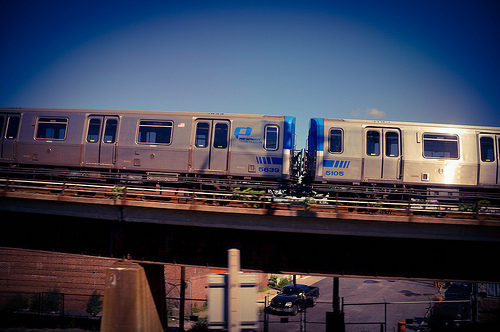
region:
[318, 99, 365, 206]
gray elevated train on track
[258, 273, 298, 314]
black pick up truck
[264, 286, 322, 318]
black truck under bridge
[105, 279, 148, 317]
concrete support partition of bridge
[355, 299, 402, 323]
fence is under bridge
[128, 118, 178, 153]
window of gray train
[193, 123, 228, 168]
doors of elevated train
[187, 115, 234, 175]
Silver automatic doors on a silver train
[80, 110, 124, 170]
Silver automatic doors on a silver train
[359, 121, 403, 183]
Silver automatic doors on a silver train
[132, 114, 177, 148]
Passenger window on a silver train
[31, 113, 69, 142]
Passenger window on a silver train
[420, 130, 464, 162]
Passenger window on a silver train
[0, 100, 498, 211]
Silver passenger train traveling down track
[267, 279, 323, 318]
Black ford pickup on the road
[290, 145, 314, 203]
Connection parts of a silver train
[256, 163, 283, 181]
Number 5639 written on a silver train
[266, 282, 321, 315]
a black truck with a silver bumper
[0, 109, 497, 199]
a silver train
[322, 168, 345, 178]
the number 5105 in blue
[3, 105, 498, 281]
silver train on a bridge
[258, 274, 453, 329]
truck on the roadway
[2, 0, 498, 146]
a small cloud in a blue sky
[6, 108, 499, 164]
a line of windows on a train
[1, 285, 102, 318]
shrubs growing next to a building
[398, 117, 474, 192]
sun shining against a silver train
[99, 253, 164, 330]
concrete bridge support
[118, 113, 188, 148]
Window of a train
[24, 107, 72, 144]
Window of a train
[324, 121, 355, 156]
Window of a train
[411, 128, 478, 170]
Window of a train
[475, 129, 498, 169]
Window of a train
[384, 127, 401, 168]
Window of a train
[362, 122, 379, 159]
Window of a train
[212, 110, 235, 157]
Window of a train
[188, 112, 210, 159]
Window of a train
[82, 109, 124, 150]
Window of a train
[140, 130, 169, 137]
window on the train.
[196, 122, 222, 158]
doors on the train.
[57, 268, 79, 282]
wall made of brick.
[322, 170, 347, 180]
number on the train.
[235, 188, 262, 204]
weeds near the train.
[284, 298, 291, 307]
headlight on the truck.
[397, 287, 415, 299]
condensation on the road.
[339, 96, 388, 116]
cloud in the sky.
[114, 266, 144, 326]
concrete support under bridge.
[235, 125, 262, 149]
logo on the train.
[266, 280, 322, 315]
a black pick up truck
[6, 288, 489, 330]
a chain link fence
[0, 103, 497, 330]
a train on a overpath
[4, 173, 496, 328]
a train track on a overpath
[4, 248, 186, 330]
a brown stone wall